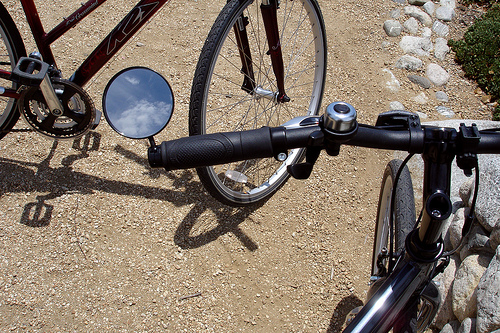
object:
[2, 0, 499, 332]
ground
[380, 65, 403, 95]
rock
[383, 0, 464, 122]
stones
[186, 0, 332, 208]
tire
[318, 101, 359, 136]
bell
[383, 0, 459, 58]
rock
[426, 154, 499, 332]
stones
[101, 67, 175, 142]
mirror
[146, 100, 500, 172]
handlebars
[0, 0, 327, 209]
bicycle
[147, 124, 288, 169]
handlebar grip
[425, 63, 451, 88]
rock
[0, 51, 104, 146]
pedal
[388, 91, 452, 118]
rock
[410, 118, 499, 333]
rocks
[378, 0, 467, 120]
rocks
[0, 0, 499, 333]
dirt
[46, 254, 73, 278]
rock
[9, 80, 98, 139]
chain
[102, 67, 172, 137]
reflection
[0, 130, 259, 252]
shadow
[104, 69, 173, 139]
clouds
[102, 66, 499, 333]
bicycle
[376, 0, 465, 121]
path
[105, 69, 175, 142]
sky